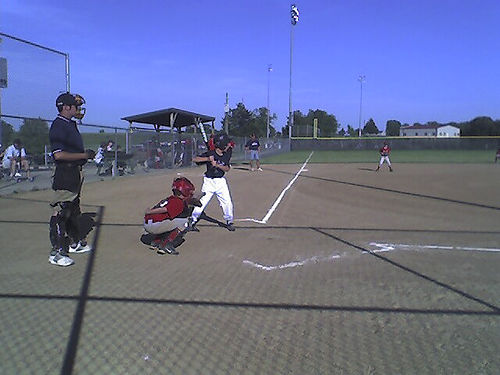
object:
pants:
[192, 177, 234, 224]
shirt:
[197, 150, 230, 178]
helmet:
[170, 177, 194, 197]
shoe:
[45, 252, 75, 267]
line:
[262, 150, 315, 224]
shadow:
[1, 218, 499, 375]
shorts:
[249, 150, 258, 162]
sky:
[0, 0, 500, 133]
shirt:
[2, 146, 27, 165]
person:
[244, 133, 261, 171]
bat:
[195, 117, 217, 169]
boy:
[144, 177, 195, 256]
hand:
[156, 207, 170, 212]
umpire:
[49, 91, 93, 267]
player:
[375, 141, 392, 171]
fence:
[290, 136, 500, 150]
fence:
[1, 114, 286, 194]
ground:
[0, 149, 500, 374]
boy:
[186, 137, 236, 232]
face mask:
[73, 93, 88, 127]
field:
[0, 150, 499, 374]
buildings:
[402, 121, 464, 149]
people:
[1, 139, 26, 178]